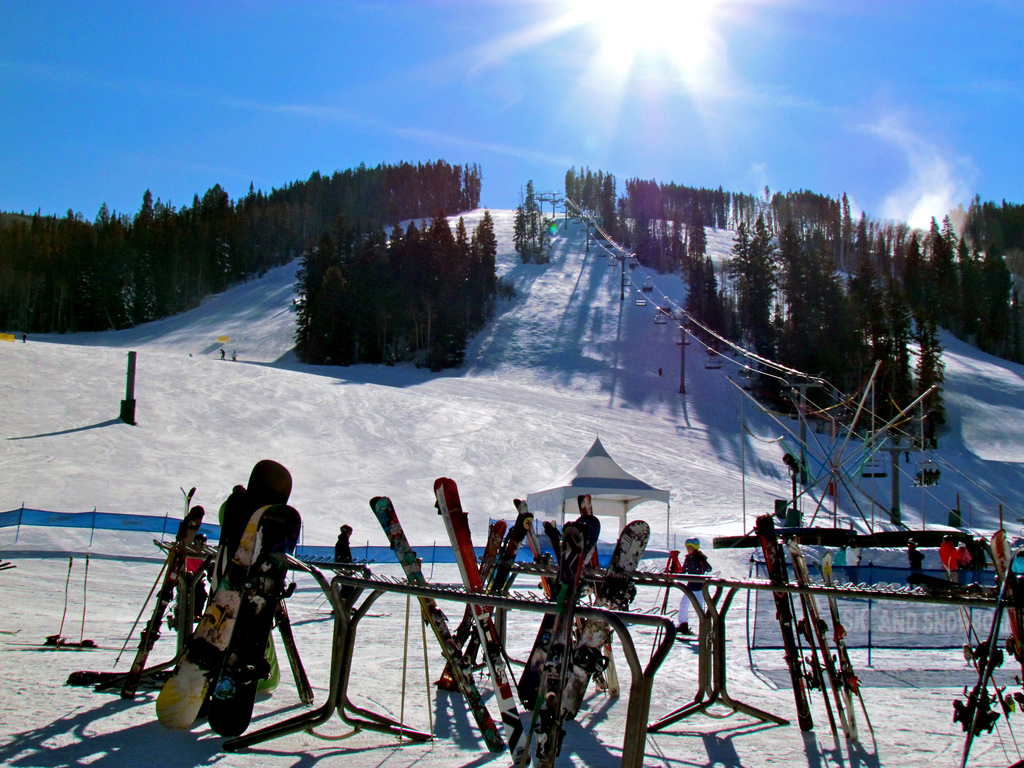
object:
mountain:
[0, 174, 1021, 767]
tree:
[125, 181, 197, 325]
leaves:
[399, 264, 404, 268]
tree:
[302, 203, 505, 373]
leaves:
[885, 326, 889, 331]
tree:
[472, 205, 507, 325]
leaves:
[1000, 317, 1001, 321]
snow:
[2, 197, 1024, 765]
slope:
[2, 207, 1019, 673]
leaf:
[803, 235, 805, 237]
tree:
[512, 178, 551, 261]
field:
[0, 154, 1022, 455]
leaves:
[823, 317, 826, 318]